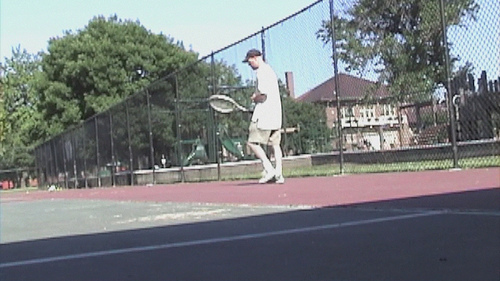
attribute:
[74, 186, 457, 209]
side lines — red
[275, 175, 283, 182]
shoe — white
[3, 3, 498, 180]
leaves — green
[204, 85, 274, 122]
racket — white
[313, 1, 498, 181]
tree — large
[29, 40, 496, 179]
fence — tall , long, chain link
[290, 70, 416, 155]
house — brick, tan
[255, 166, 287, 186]
shoes — men's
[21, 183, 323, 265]
floor — Green 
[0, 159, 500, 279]
tennis court — green, white , red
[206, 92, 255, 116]
tennis racket — white 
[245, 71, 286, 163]
outfit — light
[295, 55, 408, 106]
roof — brown